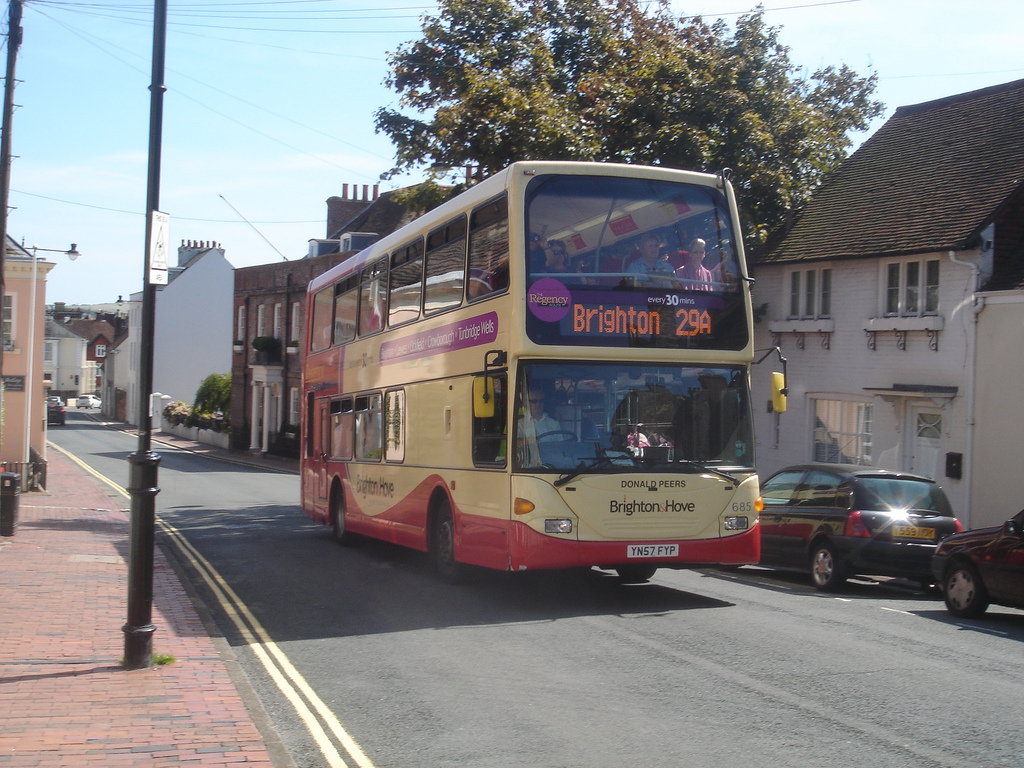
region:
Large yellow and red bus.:
[287, 148, 763, 578]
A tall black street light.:
[123, 20, 163, 657]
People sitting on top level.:
[529, 223, 730, 297]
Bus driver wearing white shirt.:
[509, 407, 567, 484]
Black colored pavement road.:
[319, 606, 950, 758]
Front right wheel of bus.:
[408, 492, 473, 572]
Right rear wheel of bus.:
[311, 475, 360, 551]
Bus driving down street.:
[295, 163, 786, 565]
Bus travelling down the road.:
[278, 164, 795, 588]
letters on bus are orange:
[568, 294, 734, 348]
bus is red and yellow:
[262, 171, 835, 568]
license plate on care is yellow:
[889, 519, 950, 551]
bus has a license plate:
[615, 534, 714, 566]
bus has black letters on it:
[583, 494, 721, 523]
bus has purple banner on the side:
[368, 304, 520, 368]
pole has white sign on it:
[140, 191, 180, 281]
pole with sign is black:
[118, 33, 163, 662]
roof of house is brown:
[810, 82, 985, 339]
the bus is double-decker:
[275, 126, 794, 611]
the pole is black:
[113, 8, 200, 677]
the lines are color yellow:
[195, 533, 372, 761]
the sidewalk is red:
[3, 479, 273, 765]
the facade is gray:
[743, 81, 1022, 480]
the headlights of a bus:
[537, 507, 756, 553]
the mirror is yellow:
[455, 337, 512, 432]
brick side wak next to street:
[2, 439, 282, 766]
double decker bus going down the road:
[288, 154, 801, 584]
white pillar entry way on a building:
[244, 361, 287, 461]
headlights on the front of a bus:
[541, 511, 763, 543]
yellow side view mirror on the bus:
[750, 345, 789, 413]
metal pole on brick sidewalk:
[117, 0, 171, 669]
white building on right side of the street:
[748, 75, 1021, 532]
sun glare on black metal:
[868, 500, 919, 526]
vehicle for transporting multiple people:
[292, 157, 789, 582]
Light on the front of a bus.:
[537, 513, 577, 539]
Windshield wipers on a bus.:
[547, 446, 738, 497]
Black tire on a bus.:
[416, 474, 475, 585]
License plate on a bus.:
[620, 534, 682, 566]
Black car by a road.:
[736, 446, 951, 606]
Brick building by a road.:
[221, 243, 352, 479]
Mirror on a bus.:
[464, 358, 503, 420]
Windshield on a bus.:
[506, 174, 731, 380]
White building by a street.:
[104, 255, 257, 448]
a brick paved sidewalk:
[8, 448, 259, 763]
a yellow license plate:
[892, 524, 937, 540]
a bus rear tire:
[327, 486, 348, 538]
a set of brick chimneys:
[326, 180, 381, 235]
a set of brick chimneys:
[178, 240, 224, 269]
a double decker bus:
[298, 155, 790, 580]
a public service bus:
[295, 161, 786, 588]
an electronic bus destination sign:
[564, 300, 714, 340]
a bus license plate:
[623, 543, 678, 557]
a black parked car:
[759, 462, 956, 590]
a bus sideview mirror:
[469, 372, 499, 421]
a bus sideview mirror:
[766, 370, 790, 415]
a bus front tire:
[424, 496, 464, 580]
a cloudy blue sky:
[5, 2, 1021, 303]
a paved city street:
[49, 413, 1020, 767]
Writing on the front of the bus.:
[565, 301, 664, 339]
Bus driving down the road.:
[297, 156, 765, 586]